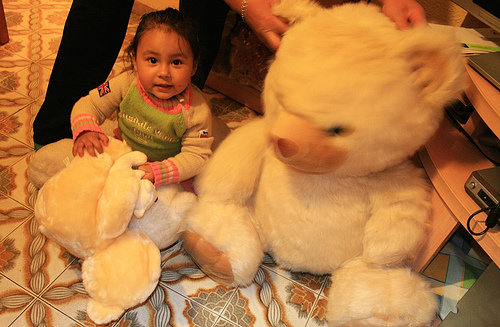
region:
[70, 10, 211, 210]
the child sitting on the ground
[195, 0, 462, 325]
the big stuffed animal sitting next to the child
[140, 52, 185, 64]
the child's two eyes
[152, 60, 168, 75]
the child's nose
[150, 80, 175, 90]
the child's mouth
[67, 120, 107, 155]
the child's right hand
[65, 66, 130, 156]
the child's right arm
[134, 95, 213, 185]
the child's left arm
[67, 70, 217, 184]
the sweater on the child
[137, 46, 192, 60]
the eyebrows on the child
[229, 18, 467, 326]
big teddy bear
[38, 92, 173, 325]
toddler holding a teddy bear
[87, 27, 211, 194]
toddler is wearing a sweater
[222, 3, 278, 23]
person wearing a bracelet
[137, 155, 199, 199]
pink stripes on the sleeves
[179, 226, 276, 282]
tan pad on the bear's foot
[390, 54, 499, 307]
shelves next to bear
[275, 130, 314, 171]
bear has a tan nose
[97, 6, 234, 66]
toddler has black hair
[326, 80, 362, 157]
bear has black eyes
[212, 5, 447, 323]
large white stuffed bear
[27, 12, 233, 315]
small child sitting on floor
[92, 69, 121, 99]
design on sleeve of child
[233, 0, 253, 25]
bracelet on wrist of person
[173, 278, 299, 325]
design on floor tile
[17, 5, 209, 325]
child holding stuffed animal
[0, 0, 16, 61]
brown wooden chair leg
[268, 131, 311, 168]
pink nose of stuffed white bear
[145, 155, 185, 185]
stripes on sleeve of child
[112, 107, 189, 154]
writing on front of shirt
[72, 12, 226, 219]
child sitting on floor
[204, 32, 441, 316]
stuffed bear on floor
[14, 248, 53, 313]
design on floor tile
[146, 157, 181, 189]
pink stripes on sleeve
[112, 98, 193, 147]
green on front of sweater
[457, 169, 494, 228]
electronics on wood shelf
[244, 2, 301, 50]
hand on side of bear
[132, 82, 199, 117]
pink collar on sweater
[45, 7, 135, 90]
black pants on leg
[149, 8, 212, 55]
black hair on girl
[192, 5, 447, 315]
a big teddy bear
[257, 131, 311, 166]
the nose is brown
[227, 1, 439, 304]
the bear is blurry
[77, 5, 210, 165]
the little girl is looking at the camera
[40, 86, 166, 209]
the girl is touching a teddy bear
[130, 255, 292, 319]
the floor is patterned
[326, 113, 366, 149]
the eye is black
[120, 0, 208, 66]
the girl`s hair is black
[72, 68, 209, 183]
the sweater is pink and green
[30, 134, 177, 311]
the bear is yellowish